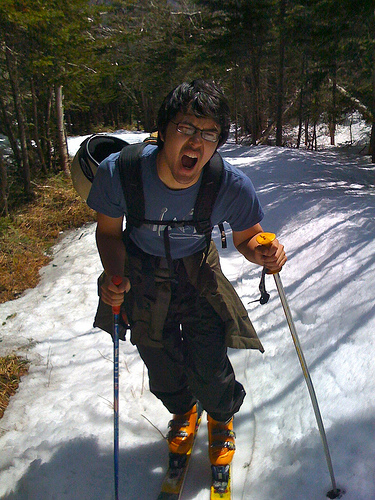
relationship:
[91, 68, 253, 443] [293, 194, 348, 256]
person standing in snow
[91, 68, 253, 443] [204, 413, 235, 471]
person wearing a left foot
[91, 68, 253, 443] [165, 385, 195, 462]
person wearing a shoe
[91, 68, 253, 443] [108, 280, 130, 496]
person holding ski rod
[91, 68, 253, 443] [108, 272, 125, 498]
person holding ski rod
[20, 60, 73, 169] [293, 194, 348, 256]
tree near snow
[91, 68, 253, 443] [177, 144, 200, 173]
person with open mouth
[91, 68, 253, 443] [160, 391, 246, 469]
person wearing orange boots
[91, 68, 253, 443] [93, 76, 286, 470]
person who person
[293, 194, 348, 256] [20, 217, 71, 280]
snow on ground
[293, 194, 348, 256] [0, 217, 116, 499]
snow that snow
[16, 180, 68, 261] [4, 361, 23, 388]
grass that brown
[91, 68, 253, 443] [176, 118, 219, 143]
person wearing glasses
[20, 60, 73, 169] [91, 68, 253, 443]
tree behind person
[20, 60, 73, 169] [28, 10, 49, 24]
tree that green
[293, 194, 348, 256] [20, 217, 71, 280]
snow that on ground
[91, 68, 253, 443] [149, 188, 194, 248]
person wearing blue shirt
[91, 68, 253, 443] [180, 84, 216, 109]
person with dark hair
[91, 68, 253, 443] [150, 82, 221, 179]
person with a head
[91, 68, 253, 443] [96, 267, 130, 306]
person with right hand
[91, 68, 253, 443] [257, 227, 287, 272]
person with left hand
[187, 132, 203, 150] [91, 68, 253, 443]
nose of a person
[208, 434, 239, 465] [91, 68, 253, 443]
left foot of a person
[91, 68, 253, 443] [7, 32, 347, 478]
person in picture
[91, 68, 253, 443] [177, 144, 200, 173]
person with an open mouth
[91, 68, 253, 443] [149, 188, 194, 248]
person wearing a blue shirt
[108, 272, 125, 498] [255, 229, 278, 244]
ski rod with yellow tip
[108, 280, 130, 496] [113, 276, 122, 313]
ski rod with red top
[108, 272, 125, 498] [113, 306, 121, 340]
ski rod that are coloured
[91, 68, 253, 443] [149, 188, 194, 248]
person in blue shirt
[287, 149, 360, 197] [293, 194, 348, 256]
shadow of tree in snow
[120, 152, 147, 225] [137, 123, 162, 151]
straps of black pack